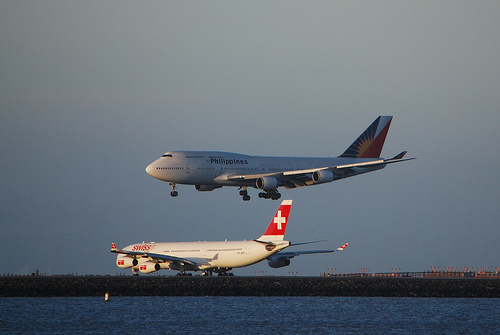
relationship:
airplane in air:
[143, 110, 423, 204] [1, 1, 499, 280]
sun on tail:
[345, 128, 374, 160] [338, 113, 395, 159]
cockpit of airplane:
[156, 151, 182, 162] [143, 110, 423, 204]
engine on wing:
[252, 174, 278, 191] [219, 155, 429, 186]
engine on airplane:
[192, 181, 226, 192] [143, 110, 423, 204]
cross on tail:
[273, 211, 287, 232] [263, 198, 298, 241]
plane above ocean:
[106, 197, 352, 278] [2, 295, 499, 335]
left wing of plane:
[109, 241, 195, 267] [106, 197, 352, 278]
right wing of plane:
[279, 241, 349, 255] [106, 197, 352, 278]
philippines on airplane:
[208, 155, 253, 168] [143, 110, 423, 204]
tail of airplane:
[338, 113, 395, 159] [143, 110, 423, 204]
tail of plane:
[263, 198, 298, 241] [106, 197, 352, 278]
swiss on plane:
[132, 243, 155, 253] [106, 197, 352, 278]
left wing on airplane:
[219, 155, 429, 186] [143, 110, 423, 204]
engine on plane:
[138, 262, 160, 274] [106, 197, 352, 278]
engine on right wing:
[264, 257, 293, 268] [279, 241, 349, 255]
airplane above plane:
[143, 110, 423, 204] [106, 197, 352, 278]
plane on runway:
[106, 197, 352, 278] [4, 279, 498, 285]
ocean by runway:
[2, 295, 499, 335] [4, 279, 498, 285]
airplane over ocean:
[143, 110, 423, 204] [2, 295, 499, 335]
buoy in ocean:
[101, 291, 111, 304] [2, 295, 499, 335]